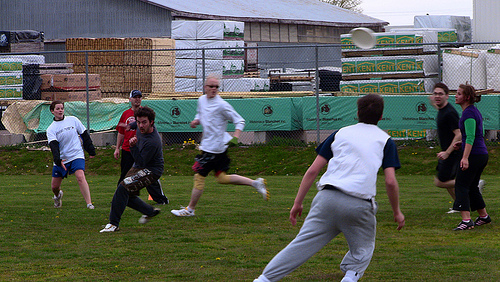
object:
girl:
[450, 82, 492, 233]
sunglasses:
[204, 83, 222, 90]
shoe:
[251, 176, 272, 202]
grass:
[0, 137, 499, 282]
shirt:
[313, 120, 403, 201]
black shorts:
[190, 148, 235, 180]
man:
[112, 89, 170, 206]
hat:
[127, 89, 144, 99]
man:
[169, 76, 271, 218]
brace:
[191, 173, 207, 192]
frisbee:
[347, 25, 378, 50]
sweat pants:
[260, 185, 379, 281]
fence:
[0, 31, 499, 150]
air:
[382, 7, 411, 19]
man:
[249, 91, 410, 281]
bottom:
[259, 176, 271, 204]